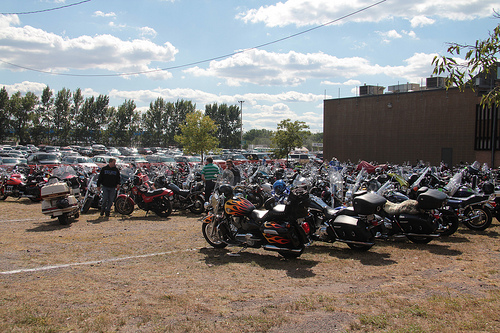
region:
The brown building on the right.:
[324, 95, 499, 160]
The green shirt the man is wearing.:
[199, 163, 221, 177]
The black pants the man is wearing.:
[201, 180, 218, 205]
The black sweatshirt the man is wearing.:
[98, 163, 122, 188]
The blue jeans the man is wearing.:
[96, 189, 113, 214]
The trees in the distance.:
[4, 88, 254, 145]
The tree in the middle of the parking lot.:
[178, 111, 218, 171]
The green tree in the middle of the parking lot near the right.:
[274, 116, 311, 152]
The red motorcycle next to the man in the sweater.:
[117, 171, 173, 221]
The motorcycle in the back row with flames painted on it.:
[204, 195, 306, 263]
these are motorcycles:
[65, 68, 434, 279]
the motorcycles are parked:
[157, 154, 350, 299]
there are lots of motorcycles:
[78, 125, 412, 314]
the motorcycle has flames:
[204, 198, 302, 255]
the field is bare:
[95, 239, 219, 329]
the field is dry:
[88, 248, 176, 324]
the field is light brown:
[41, 219, 186, 313]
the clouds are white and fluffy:
[70, 23, 285, 99]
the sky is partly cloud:
[108, 14, 330, 104]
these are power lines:
[24, 14, 226, 141]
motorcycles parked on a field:
[3, 129, 498, 268]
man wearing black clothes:
[84, 139, 136, 226]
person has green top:
[194, 154, 231, 211]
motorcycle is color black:
[190, 175, 334, 267]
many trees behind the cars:
[1, 78, 267, 172]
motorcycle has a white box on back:
[33, 164, 84, 228]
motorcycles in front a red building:
[294, 55, 499, 225]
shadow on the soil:
[186, 240, 468, 292]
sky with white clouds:
[1, 1, 489, 88]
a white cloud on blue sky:
[183, 44, 373, 84]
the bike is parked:
[197, 195, 309, 259]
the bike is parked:
[300, 173, 394, 270]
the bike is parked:
[34, 169, 86, 219]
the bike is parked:
[118, 149, 180, 213]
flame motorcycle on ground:
[198, 175, 300, 261]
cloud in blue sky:
[3, 25, 186, 81]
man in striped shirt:
[194, 157, 224, 221]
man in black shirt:
[93, 146, 129, 228]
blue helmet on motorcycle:
[273, 165, 293, 205]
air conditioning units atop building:
[346, 72, 453, 97]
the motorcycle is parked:
[200, 168, 317, 265]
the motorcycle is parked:
[37, 163, 82, 224]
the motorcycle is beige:
[41, 163, 83, 222]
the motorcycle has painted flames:
[202, 166, 309, 258]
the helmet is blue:
[273, 178, 286, 194]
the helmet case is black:
[351, 190, 385, 215]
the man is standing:
[96, 158, 118, 217]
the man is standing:
[203, 155, 218, 200]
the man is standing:
[223, 160, 240, 183]